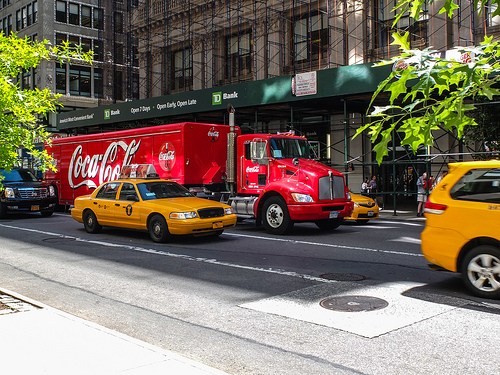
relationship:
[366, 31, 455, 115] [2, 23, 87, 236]
green leaves from tree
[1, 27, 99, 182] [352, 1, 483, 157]
green leaves on tree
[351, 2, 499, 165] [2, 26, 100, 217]
green leaves on tree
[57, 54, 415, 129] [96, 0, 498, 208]
sign on td bank building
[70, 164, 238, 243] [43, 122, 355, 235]
taxi cab next to red truck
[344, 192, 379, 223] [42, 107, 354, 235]
taxi cab next to truck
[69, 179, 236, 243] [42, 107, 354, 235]
taxi cab next to truck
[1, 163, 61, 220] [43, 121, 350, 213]
black suv next to red truck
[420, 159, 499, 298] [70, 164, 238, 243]
taxi cab in front of taxi cab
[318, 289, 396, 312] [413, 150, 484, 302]
manhole next to taxi cab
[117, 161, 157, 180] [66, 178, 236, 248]
advertisement on top of taxi cab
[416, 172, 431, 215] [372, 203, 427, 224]
person standing on sidewalk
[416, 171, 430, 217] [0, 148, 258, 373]
person standing on sidewalk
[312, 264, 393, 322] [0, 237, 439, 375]
man holes on road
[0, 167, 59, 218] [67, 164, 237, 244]
black suv behind taxi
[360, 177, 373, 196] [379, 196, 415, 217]
pedestrians standing on sidewalk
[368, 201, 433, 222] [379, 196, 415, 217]
person standing on sidewalk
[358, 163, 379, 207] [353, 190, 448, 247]
pedestrians walking on sidewalk